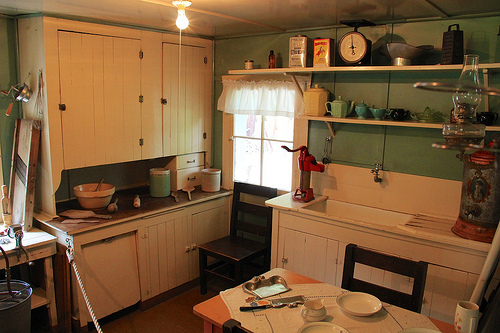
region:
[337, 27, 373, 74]
A clock is on the top shelf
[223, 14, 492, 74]
The shelf has several items on it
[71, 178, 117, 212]
A bowl is on the counter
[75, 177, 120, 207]
A spoon is in the bowl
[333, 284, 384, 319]
A empty plate is on the table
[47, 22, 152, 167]
The cabinet door is closed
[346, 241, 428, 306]
The chair appears to be made out of wood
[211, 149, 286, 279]
A chair near the window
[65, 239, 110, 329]
A rope attached to the cabinets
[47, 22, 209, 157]
The cabinets are a white color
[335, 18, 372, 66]
A large kitchen scale.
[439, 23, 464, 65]
A rusty box grater.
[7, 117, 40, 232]
A giant mandoline made from wood and metal.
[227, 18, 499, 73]
Miscellaneous items are on the top shelf.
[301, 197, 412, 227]
A long and deep sink.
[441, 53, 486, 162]
An antique oil lamp.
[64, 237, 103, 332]
A rope that is sectioning off the kitchen.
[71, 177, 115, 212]
A large ceramic bowl with a spoon in it.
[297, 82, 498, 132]
A shelf with teapots and other ceramic items on it.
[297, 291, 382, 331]
Two white bowls on the table.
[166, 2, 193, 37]
A light bulb is turned on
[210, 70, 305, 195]
White curtains over a window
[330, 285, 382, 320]
A round white plate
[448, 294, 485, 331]
A white coffee mug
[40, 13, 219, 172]
White and wooden cabinets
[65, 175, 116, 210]
A large beige bowl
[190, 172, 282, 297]
A dark brown wooden chair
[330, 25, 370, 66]
A clock is round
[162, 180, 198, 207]
Two brown wooden spoons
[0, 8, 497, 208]
The walls are green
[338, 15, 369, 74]
the scale is on the shelf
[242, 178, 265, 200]
the chair is by the window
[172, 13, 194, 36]
the light is on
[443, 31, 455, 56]
the grater is black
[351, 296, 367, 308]
the bowl is empty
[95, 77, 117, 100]
the cabinet is white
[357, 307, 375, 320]
the bowl is on the table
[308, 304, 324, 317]
the pitcher is white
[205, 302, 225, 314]
the table is tan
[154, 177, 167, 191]
the canister is light green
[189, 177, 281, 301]
black wooden chair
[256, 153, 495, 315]
large white kitchen sink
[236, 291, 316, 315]
butcher knife with a black handle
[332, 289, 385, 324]
white dinner plate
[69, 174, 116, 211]
white mixing bowl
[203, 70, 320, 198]
window with white curtain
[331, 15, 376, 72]
kitchen scale on a shelf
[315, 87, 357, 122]
sea foam green kettle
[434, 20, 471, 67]
metal cheese grater on shelf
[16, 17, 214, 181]
white wooden kitchen cabinet